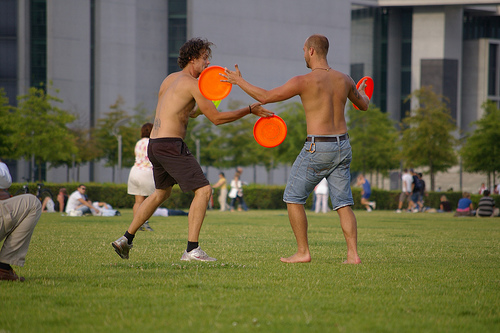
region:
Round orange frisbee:
[251, 110, 287, 146]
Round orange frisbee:
[195, 61, 230, 96]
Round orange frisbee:
[350, 75, 370, 110]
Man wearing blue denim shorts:
[215, 30, 370, 260]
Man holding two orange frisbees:
[195, 30, 375, 260]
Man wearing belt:
[215, 30, 370, 260]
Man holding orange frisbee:
[105, 35, 285, 265]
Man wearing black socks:
[106, 30, 271, 260]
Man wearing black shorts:
[105, 30, 266, 261]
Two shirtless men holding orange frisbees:
[105, 32, 373, 267]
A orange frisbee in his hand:
[199, 65, 231, 102]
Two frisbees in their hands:
[199, 58, 286, 147]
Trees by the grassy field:
[357, 100, 452, 167]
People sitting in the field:
[456, 186, 491, 214]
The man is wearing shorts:
[290, 135, 355, 205]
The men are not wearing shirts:
[152, 71, 362, 137]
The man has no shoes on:
[278, 249, 362, 264]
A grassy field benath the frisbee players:
[220, 210, 276, 326]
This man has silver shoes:
[111, 238, 215, 260]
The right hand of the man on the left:
[249, 100, 272, 118]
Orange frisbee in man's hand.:
[192, 62, 249, 117]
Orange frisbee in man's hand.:
[247, 108, 308, 167]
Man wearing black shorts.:
[136, 120, 214, 197]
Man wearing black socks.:
[119, 217, 226, 256]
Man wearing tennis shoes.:
[113, 241, 274, 298]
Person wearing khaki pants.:
[10, 190, 65, 265]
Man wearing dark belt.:
[301, 130, 366, 137]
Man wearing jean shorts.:
[301, 139, 369, 217]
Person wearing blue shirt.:
[453, 192, 481, 205]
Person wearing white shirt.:
[397, 169, 420, 193]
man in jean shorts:
[305, 131, 368, 243]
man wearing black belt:
[301, 125, 378, 182]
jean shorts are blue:
[309, 174, 406, 241]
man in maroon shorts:
[143, 153, 213, 199]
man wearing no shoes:
[286, 245, 358, 269]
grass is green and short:
[256, 262, 300, 299]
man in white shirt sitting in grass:
[68, 187, 117, 220]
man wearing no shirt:
[301, 68, 338, 132]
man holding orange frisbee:
[256, 110, 302, 163]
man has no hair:
[304, 36, 345, 73]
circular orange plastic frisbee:
[250, 111, 287, 147]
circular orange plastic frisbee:
[350, 70, 377, 115]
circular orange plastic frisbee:
[195, 64, 237, 101]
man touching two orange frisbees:
[193, 31, 382, 274]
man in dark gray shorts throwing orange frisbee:
[93, 33, 291, 270]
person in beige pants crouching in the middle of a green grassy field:
[0, 145, 50, 297]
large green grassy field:
[0, 196, 498, 332]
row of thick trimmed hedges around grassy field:
[1, 182, 498, 214]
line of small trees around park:
[0, 73, 498, 215]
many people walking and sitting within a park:
[15, 113, 498, 223]